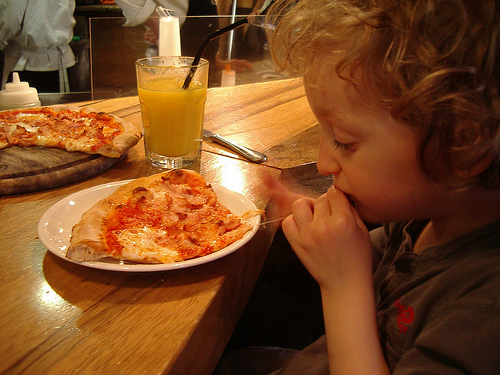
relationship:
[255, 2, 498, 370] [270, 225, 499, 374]
boy wearing brown shirt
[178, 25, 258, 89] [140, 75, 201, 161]
straw on beverage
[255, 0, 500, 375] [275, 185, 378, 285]
boy on hand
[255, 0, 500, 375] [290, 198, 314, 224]
boy has finger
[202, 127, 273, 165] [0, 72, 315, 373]
spoon on table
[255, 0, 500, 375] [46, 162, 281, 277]
boy eats pizza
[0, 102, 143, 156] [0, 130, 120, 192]
pizza on tray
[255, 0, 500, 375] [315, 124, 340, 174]
boy has nose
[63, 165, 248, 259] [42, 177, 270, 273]
cheese pizza on plate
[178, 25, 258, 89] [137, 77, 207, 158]
straw on beverage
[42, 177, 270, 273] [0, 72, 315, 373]
plate on table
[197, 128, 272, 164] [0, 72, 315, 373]
butter knife on table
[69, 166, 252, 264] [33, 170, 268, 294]
pizza on plate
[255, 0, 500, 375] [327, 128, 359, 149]
boy has eye